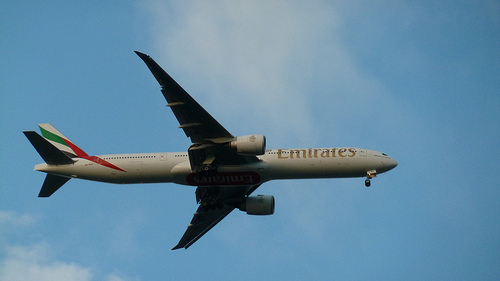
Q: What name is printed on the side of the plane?
A: Emirates.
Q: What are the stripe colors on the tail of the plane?
A: Red, green, white.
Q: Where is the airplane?
A: In the sky.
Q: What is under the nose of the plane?
A: Landing gear.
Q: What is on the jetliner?
A: Emirates.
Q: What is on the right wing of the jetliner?
A: The engine.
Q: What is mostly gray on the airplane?
A: The wings.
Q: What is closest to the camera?
A: The wing.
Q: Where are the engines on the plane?
A: Under the wings.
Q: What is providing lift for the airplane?
A: The wings.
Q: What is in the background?
A: White clouds.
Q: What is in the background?
A: Blue sky.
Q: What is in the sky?
A: An airplane.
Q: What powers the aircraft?
A: Jet engines.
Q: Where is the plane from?
A: Emirates.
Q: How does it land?
A: Flaps and landing gear deployed.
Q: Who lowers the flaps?
A: The pilot.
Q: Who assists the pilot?
A: The co-pilot.